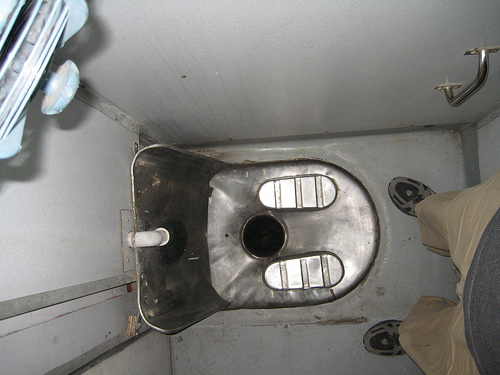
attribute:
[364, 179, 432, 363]
shoes —  black, brown 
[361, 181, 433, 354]
shoes — brown , black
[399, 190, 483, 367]
pants — brown , brown khaki 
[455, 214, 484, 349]
shirt — gray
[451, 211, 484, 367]
shirt — gray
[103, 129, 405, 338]
toilet — old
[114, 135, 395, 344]
toilet — whole 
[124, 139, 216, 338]
lid — up 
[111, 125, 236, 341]
lid — black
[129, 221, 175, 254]
tube — white 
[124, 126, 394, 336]
toilet — metal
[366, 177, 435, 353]
shoes — old , pair , gray , black  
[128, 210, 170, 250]
pipe — white 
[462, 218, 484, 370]
shirt — gray  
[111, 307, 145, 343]
piece — small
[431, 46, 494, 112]
railing — silver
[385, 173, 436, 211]
shoe — grey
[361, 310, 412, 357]
shoe — grey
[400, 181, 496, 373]
pants — tan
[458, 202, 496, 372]
shirt — gray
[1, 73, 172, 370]
wall — brown, wooden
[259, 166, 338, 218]
footprint — steel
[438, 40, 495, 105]
handle — metal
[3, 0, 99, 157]
thing — blue, plastic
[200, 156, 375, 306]
seat — steel, metal